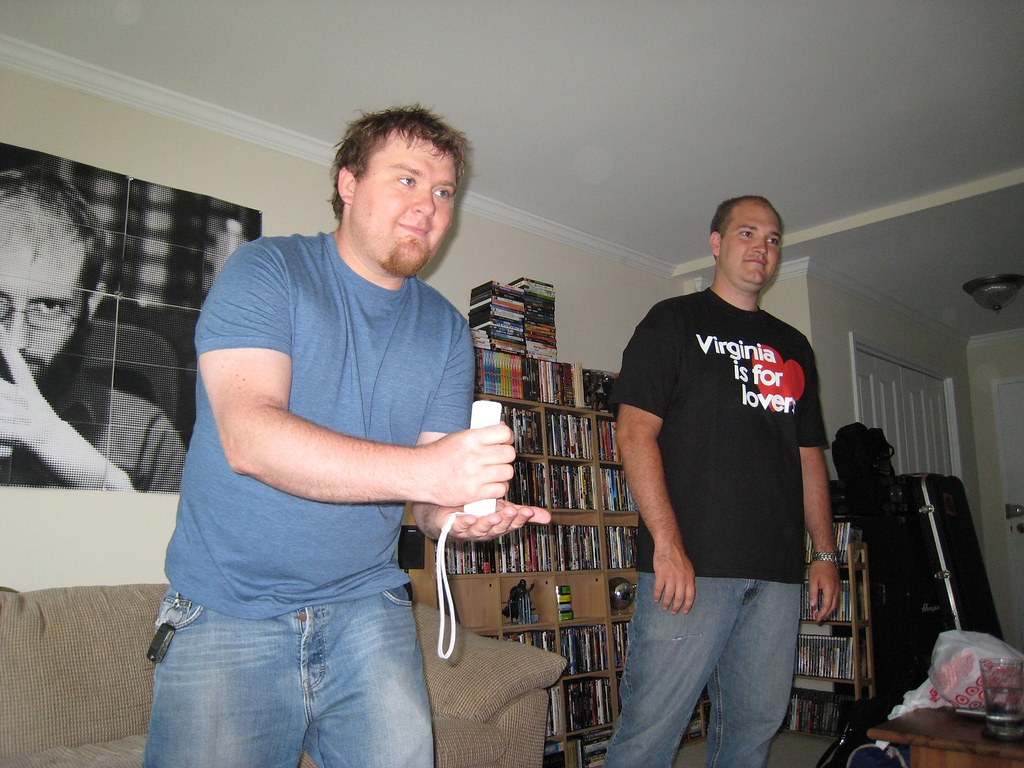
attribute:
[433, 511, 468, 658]
handle — white  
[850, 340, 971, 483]
door — white  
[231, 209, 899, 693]
shirt — blue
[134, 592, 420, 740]
jeans — blue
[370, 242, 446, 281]
beard — brown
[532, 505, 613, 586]
movie — stacked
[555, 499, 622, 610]
movie — stacked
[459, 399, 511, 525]
wii remote — white, verticle